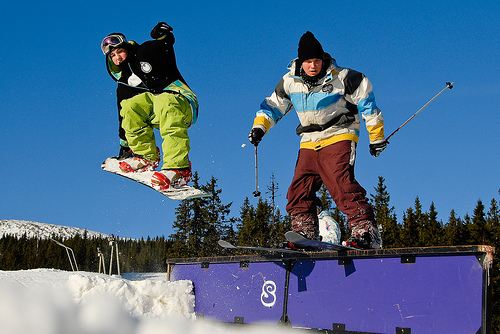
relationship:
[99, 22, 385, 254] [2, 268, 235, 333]
people in snow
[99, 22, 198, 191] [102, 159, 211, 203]
person on a snowboard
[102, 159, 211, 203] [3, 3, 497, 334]
snowboard in air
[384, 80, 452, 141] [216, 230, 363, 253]
poles are for skiing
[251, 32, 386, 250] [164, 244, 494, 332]
skier on a platform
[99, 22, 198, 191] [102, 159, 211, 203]
person has a snowboard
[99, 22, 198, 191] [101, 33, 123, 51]
person has on goggles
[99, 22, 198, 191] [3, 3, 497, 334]
person in air